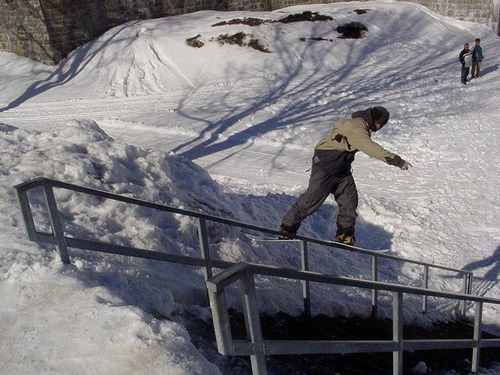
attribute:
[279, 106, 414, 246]
man — snowboarding, leaning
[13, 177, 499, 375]
railing — iron, silver, metal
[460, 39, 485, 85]
people — standing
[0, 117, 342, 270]
pile — dirty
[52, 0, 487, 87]
hill — snowy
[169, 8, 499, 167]
shadow — tree, of the tree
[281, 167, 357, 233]
pants — gray, grey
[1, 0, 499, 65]
wall — brick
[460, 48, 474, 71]
jacket — black, white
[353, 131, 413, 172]
arm — outstretched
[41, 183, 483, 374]
poles — metal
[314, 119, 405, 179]
jacket — brown